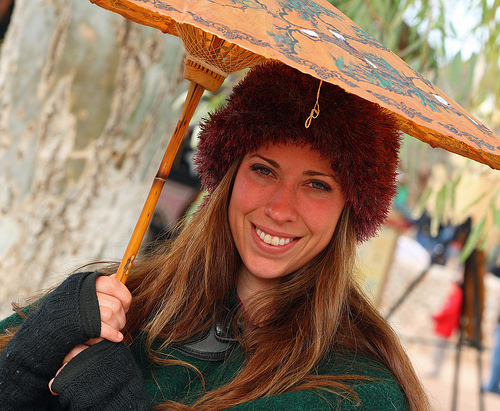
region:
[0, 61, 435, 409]
A lady with a hat.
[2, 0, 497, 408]
A lady with an umbrella.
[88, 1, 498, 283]
A little orange umbrella.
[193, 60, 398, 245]
A hat on a head.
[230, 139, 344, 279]
A girls face and smile.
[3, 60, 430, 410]
A girl with a smile.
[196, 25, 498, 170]
Decoration on an umbrella.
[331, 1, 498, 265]
Blurry green leaves.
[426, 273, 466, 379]
A blurry person behind lady.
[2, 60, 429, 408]
A lady wearing a green coat.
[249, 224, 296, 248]
the women is smiling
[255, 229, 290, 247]
white teeth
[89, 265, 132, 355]
the womens hand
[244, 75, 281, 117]
a red hat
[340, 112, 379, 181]
a hat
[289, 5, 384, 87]
an umbrella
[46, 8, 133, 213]
tree bark on the tree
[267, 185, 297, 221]
the womens nose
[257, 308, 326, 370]
the womens hair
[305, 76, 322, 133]
an orange string on the umbrella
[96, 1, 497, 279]
umbrella with bamboo pole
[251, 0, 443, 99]
painted top of umbrella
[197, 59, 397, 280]
fuzzy hat on head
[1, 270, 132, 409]
long sweater on hands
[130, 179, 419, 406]
long hair on shoulders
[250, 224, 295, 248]
white teeth in mouth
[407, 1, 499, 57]
light of daytime sky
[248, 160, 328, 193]
two eyes on face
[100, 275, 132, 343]
fingers wrapped around pole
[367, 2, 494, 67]
green leaves of tree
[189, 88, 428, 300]
woman looking at camera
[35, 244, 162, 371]
hand of the woman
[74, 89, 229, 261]
handle of the umbrella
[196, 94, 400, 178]
hat on woman's head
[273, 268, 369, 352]
hair of the woman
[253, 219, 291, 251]
teeth of the woman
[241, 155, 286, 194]
eye of the woman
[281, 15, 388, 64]
top of the umbrella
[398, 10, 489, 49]
leaves behind the woman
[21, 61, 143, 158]
tree behind the woman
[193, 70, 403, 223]
fuzzy red hat woman is wearing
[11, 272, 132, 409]
black sleeves of woman's shirt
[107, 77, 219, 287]
wooden handle of umbrella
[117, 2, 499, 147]
umbrella with scene printed on it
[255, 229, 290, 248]
teeth of woman holding umbrella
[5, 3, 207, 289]
tree trunk behind woman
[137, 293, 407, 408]
green shirt of woman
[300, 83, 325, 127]
string hanging from umbrella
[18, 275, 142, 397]
hands holding umbrella handle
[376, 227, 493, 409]
sidewalk behind the woman